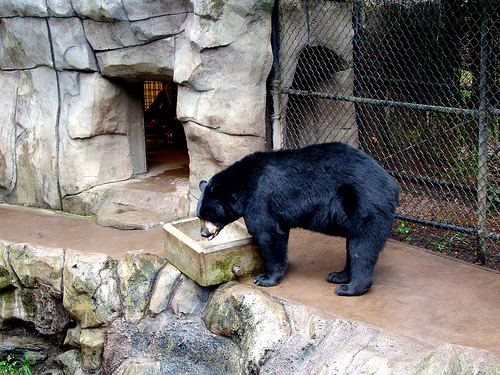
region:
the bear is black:
[196, 130, 431, 292]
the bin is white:
[153, 239, 248, 292]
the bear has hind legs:
[331, 239, 384, 290]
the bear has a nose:
[187, 217, 223, 242]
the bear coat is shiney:
[189, 137, 417, 304]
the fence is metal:
[435, 85, 498, 223]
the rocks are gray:
[81, 282, 183, 372]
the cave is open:
[116, 65, 188, 184]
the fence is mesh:
[428, 113, 459, 179]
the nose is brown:
[197, 219, 218, 241]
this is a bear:
[183, 108, 403, 295]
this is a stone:
[208, 275, 296, 370]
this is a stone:
[151, 261, 196, 325]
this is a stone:
[62, 255, 119, 336]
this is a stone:
[148, 120, 279, 227]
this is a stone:
[37, 73, 128, 143]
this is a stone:
[9, 250, 64, 307]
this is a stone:
[79, 10, 156, 78]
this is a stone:
[13, 68, 120, 185]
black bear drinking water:
[151, 136, 429, 300]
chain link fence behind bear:
[419, 160, 464, 202]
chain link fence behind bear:
[339, 95, 376, 143]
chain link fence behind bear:
[280, 100, 322, 134]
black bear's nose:
[193, 218, 217, 245]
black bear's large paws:
[324, 262, 394, 319]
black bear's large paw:
[331, 266, 372, 310]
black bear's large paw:
[325, 252, 356, 288]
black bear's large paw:
[254, 260, 286, 296]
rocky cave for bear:
[0, 5, 274, 247]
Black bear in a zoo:
[194, 138, 406, 300]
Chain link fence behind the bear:
[268, 1, 497, 271]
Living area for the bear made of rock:
[0, 1, 362, 236]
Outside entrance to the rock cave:
[86, 58, 193, 200]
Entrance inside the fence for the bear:
[276, 40, 353, 157]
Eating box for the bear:
[160, 212, 263, 292]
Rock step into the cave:
[83, 183, 198, 233]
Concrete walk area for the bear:
[0, 200, 498, 360]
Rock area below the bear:
[0, 239, 498, 374]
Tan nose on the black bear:
[195, 215, 220, 243]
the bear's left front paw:
[253, 260, 285, 289]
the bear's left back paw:
[336, 281, 376, 300]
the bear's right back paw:
[327, 271, 354, 286]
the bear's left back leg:
[349, 236, 379, 274]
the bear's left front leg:
[249, 216, 284, 263]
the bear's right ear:
[192, 177, 211, 199]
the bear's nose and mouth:
[198, 227, 217, 242]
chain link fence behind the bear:
[279, 16, 498, 263]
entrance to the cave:
[84, 58, 216, 207]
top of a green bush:
[0, 351, 35, 373]